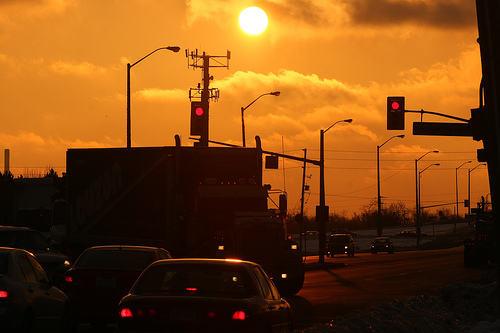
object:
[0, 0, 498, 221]
sky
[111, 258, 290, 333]
car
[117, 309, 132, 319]
brake light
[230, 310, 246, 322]
brake light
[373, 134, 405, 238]
street light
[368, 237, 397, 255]
car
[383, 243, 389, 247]
lights on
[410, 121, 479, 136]
street sign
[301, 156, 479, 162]
power lines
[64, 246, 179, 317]
cars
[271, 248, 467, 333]
road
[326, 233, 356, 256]
cars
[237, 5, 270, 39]
sun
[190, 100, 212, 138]
traffic light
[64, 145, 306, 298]
truck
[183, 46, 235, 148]
tower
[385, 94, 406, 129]
traffic light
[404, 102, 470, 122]
pole